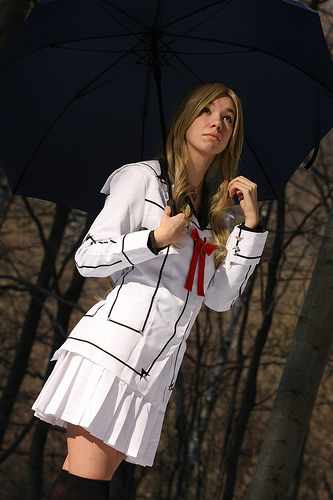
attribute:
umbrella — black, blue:
[10, 1, 332, 212]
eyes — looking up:
[199, 104, 233, 123]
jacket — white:
[74, 160, 271, 406]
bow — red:
[185, 228, 212, 295]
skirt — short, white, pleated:
[39, 353, 167, 468]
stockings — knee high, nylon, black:
[53, 470, 113, 499]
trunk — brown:
[237, 212, 332, 499]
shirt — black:
[240, 222, 265, 236]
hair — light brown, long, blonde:
[164, 83, 244, 264]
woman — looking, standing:
[34, 85, 267, 467]